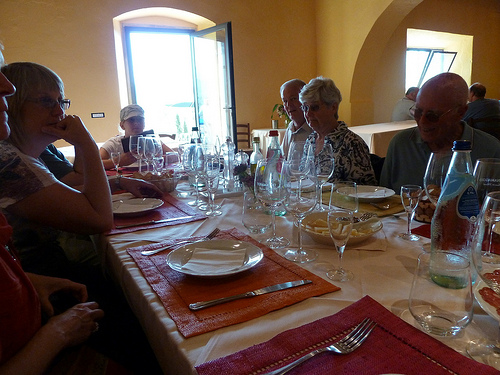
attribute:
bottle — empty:
[432, 143, 487, 253]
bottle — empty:
[428, 135, 487, 294]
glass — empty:
[404, 240, 479, 346]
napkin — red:
[181, 244, 255, 288]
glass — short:
[397, 185, 422, 239]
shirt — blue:
[373, 119, 499, 199]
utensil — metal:
[185, 276, 313, 312]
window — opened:
[395, 42, 453, 92]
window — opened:
[123, 26, 245, 148]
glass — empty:
[320, 200, 364, 280]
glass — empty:
[281, 164, 321, 258]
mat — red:
[122, 225, 340, 340]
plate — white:
[161, 230, 266, 280]